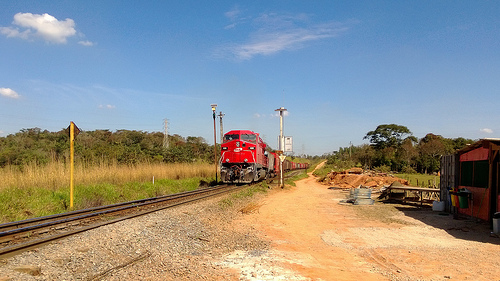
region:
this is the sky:
[392, 5, 460, 68]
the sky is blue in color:
[410, 20, 467, 85]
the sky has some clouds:
[7, 7, 362, 61]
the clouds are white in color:
[34, 13, 55, 34]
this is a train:
[220, 128, 306, 176]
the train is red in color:
[224, 141, 246, 160]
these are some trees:
[95, 130, 136, 167]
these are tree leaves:
[100, 132, 151, 157]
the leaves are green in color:
[111, 132, 143, 151]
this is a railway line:
[0, 182, 231, 245]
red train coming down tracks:
[207, 120, 306, 192]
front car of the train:
[209, 125, 271, 190]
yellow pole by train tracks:
[58, 120, 90, 207]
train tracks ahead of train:
[4, 173, 232, 268]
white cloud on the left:
[8, 6, 86, 53]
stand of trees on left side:
[8, 117, 203, 165]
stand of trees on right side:
[323, 118, 472, 175]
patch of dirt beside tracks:
[269, 160, 443, 280]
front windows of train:
[220, 133, 253, 145]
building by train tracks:
[435, 135, 492, 217]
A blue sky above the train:
[113, 52, 195, 109]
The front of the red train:
[223, 130, 260, 182]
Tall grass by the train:
[85, 166, 140, 190]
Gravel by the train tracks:
[117, 233, 192, 268]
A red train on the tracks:
[213, 156, 311, 177]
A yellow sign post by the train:
[64, 125, 78, 206]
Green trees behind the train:
[366, 136, 433, 166]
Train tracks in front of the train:
[36, 198, 190, 228]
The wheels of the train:
[254, 166, 271, 180]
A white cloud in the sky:
[17, 9, 72, 42]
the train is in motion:
[221, 127, 265, 179]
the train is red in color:
[218, 127, 263, 182]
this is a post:
[272, 100, 291, 180]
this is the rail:
[143, 192, 170, 215]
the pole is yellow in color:
[60, 124, 81, 206]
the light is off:
[275, 105, 291, 116]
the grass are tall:
[119, 160, 149, 177]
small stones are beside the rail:
[156, 208, 200, 247]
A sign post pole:
[60, 117, 93, 217]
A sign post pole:
[273, 98, 290, 195]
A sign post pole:
[208, 100, 220, 193]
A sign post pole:
[215, 102, 236, 189]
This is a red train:
[219, 120, 316, 200]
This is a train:
[220, 123, 322, 189]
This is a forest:
[0, 120, 228, 167]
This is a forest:
[319, 115, 469, 172]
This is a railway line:
[0, 180, 245, 244]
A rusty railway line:
[2, 183, 237, 263]